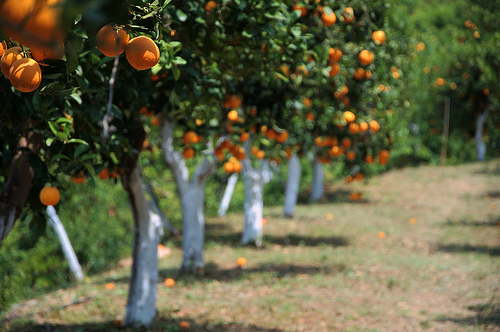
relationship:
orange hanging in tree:
[124, 31, 161, 69] [4, 1, 174, 331]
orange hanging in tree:
[91, 22, 130, 59] [4, 1, 174, 331]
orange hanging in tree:
[39, 181, 60, 206] [4, 1, 174, 331]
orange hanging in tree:
[10, 57, 42, 92] [4, 1, 174, 331]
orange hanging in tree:
[0, 42, 27, 77] [4, 1, 174, 331]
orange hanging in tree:
[34, 181, 64, 211] [4, 1, 174, 331]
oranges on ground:
[113, 27, 178, 79] [90, 220, 380, 328]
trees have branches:
[3, 0, 281, 327] [86, 62, 131, 140]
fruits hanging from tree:
[107, 34, 163, 78] [69, 14, 176, 329]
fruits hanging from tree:
[333, 40, 367, 80] [322, 29, 378, 195]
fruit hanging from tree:
[370, 27, 385, 43] [328, 0, 398, 152]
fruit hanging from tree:
[357, 47, 372, 62] [328, 0, 398, 152]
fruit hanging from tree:
[325, 47, 342, 62] [328, 0, 398, 152]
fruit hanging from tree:
[327, 62, 343, 74] [328, 0, 398, 152]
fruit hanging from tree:
[340, 110, 355, 125] [328, 0, 398, 152]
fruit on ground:
[164, 270, 174, 291] [2, 166, 498, 330]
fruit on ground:
[235, 256, 244, 268] [2, 166, 498, 330]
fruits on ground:
[213, 252, 253, 274] [218, 222, 327, 321]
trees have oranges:
[3, 2, 484, 328] [0, 8, 493, 194]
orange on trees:
[125, 35, 159, 70] [3, 2, 484, 328]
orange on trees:
[97, 22, 128, 56] [3, 2, 484, 328]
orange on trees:
[8, 56, 42, 91] [3, 2, 484, 328]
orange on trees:
[41, 187, 59, 204] [3, 2, 484, 328]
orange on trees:
[374, 30, 386, 42] [3, 2, 484, 328]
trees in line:
[216, 60, 318, 162] [34, 25, 348, 233]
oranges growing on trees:
[97, 26, 161, 70] [29, 10, 383, 238]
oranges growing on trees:
[328, 44, 345, 74] [29, 10, 383, 238]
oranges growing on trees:
[355, 46, 372, 86] [29, 10, 383, 238]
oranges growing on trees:
[1, 46, 43, 90] [29, 10, 383, 238]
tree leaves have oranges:
[70, 99, 470, 321] [121, 27, 162, 72]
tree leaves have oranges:
[70, 99, 470, 321] [6, 52, 44, 92]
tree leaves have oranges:
[70, 99, 470, 321] [354, 43, 375, 66]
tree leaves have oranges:
[70, 99, 470, 321] [366, 30, 391, 45]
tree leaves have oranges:
[70, 99, 470, 321] [343, 112, 355, 124]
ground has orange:
[207, 157, 487, 319] [236, 255, 248, 265]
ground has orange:
[207, 157, 487, 319] [159, 276, 176, 289]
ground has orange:
[207, 157, 487, 319] [174, 321, 192, 330]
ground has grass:
[0, 160, 499, 331] [270, 242, 400, 272]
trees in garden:
[3, 2, 484, 328] [3, 1, 485, 321]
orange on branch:
[103, 35, 187, 104] [24, 143, 93, 185]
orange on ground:
[222, 257, 263, 275] [91, 210, 485, 327]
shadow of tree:
[263, 225, 342, 257] [4, 1, 174, 331]